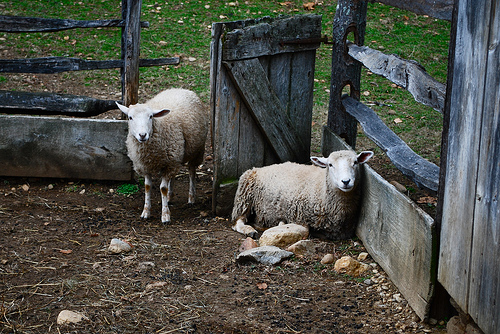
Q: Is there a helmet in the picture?
A: No, there are no helmets.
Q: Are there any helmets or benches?
A: No, there are no helmets or benches.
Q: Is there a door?
A: Yes, there is a door.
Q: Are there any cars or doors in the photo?
A: Yes, there is a door.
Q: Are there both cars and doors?
A: No, there is a door but no cars.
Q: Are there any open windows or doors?
A: Yes, there is an open door.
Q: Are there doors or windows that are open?
A: Yes, the door is open.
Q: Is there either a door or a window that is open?
A: Yes, the door is open.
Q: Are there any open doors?
A: Yes, there is an open door.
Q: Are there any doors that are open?
A: Yes, there is a door that is open.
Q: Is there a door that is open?
A: Yes, there is a door that is open.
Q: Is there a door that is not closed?
A: Yes, there is a open door.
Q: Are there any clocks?
A: No, there are no clocks.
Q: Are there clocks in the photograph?
A: No, there are no clocks.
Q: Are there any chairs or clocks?
A: No, there are no clocks or chairs.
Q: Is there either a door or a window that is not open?
A: No, there is a door but it is open.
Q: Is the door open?
A: Yes, the door is open.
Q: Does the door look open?
A: Yes, the door is open.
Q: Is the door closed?
A: No, the door is open.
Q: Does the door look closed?
A: No, the door is open.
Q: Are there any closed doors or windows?
A: No, there is a door but it is open.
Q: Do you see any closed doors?
A: No, there is a door but it is open.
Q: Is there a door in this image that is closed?
A: No, there is a door but it is open.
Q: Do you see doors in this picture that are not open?
A: No, there is a door but it is open.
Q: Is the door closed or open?
A: The door is open.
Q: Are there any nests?
A: No, there are no nests.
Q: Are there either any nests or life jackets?
A: No, there are no nests or life jackets.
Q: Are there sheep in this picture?
A: Yes, there is a sheep.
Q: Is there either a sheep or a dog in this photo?
A: Yes, there is a sheep.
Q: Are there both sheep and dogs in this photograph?
A: No, there is a sheep but no dogs.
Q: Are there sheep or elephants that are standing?
A: Yes, the sheep is standing.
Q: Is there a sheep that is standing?
A: Yes, there is a sheep that is standing.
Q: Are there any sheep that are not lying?
A: Yes, there is a sheep that is standing.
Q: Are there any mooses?
A: No, there are no mooses.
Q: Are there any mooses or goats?
A: No, there are no mooses or goats.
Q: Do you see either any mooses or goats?
A: No, there are no mooses or goats.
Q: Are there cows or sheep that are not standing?
A: No, there is a sheep but it is standing.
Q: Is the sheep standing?
A: Yes, the sheep is standing.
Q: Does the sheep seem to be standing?
A: Yes, the sheep is standing.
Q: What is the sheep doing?
A: The sheep is standing.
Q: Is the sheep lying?
A: No, the sheep is standing.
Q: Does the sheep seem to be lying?
A: No, the sheep is standing.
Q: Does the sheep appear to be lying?
A: No, the sheep is standing.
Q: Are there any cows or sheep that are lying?
A: No, there is a sheep but it is standing.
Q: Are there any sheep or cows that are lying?
A: No, there is a sheep but it is standing.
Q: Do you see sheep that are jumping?
A: No, there is a sheep but it is standing.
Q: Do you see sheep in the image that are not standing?
A: No, there is a sheep but it is standing.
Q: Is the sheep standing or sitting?
A: The sheep is standing.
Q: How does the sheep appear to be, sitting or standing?
A: The sheep is standing.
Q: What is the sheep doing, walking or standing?
A: The sheep is standing.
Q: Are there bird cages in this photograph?
A: No, there are no bird cages.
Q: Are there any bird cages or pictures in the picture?
A: No, there are no bird cages or pictures.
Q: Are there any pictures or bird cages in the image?
A: No, there are no bird cages or pictures.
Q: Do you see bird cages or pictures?
A: No, there are no bird cages or pictures.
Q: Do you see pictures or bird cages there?
A: No, there are no bird cages or pictures.